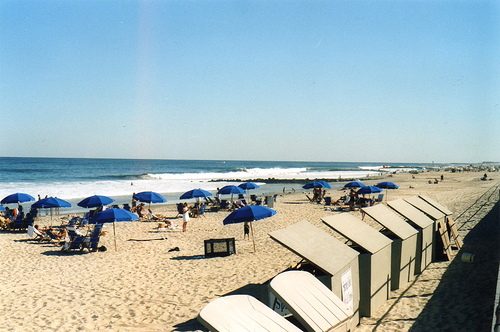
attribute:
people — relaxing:
[194, 196, 244, 215]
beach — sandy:
[5, 162, 466, 330]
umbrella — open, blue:
[93, 208, 143, 243]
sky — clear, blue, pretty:
[3, 1, 497, 161]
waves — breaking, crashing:
[136, 162, 289, 180]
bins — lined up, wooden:
[264, 194, 447, 312]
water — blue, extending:
[1, 159, 434, 195]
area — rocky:
[214, 176, 315, 187]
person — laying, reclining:
[33, 225, 69, 235]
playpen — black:
[202, 236, 237, 255]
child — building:
[168, 200, 191, 232]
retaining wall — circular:
[330, 161, 394, 184]